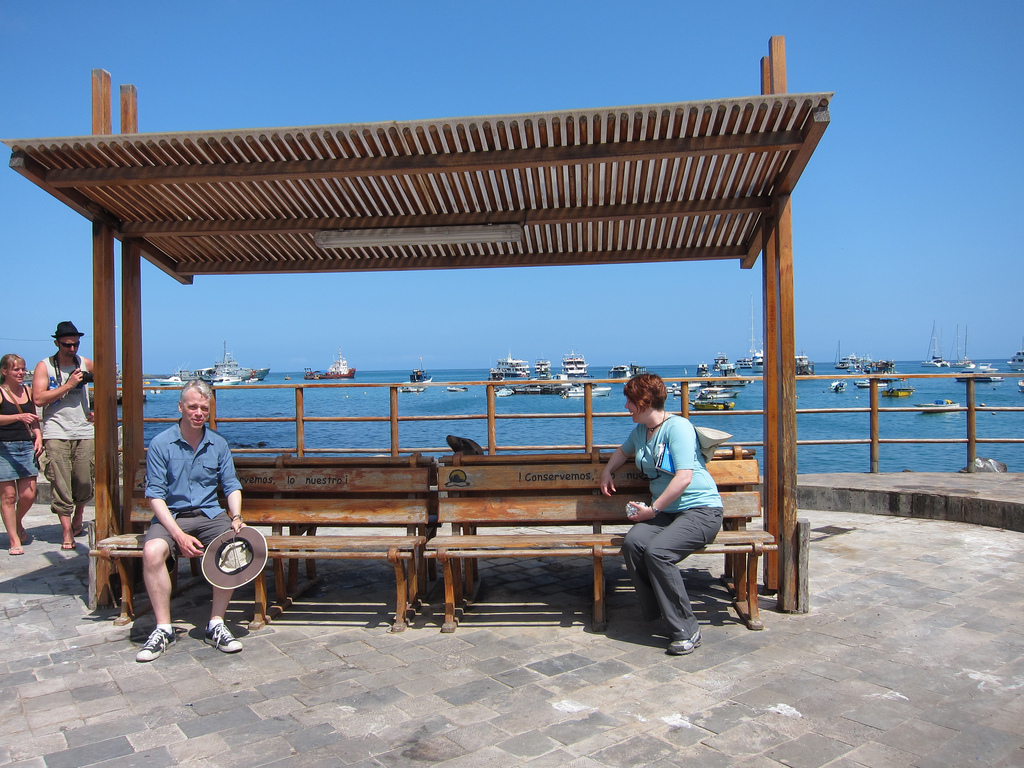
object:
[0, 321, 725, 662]
people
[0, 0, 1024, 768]
outdoors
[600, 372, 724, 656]
woman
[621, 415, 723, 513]
top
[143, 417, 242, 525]
shirt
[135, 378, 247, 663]
man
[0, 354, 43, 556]
woman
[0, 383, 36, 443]
top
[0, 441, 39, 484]
skirt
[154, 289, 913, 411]
boats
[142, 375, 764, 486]
railing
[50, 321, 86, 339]
hat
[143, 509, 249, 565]
shorts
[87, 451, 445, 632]
bench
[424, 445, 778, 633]
bench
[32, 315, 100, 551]
man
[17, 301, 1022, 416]
boat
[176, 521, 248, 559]
hand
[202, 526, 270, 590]
hat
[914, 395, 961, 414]
boat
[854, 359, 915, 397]
boat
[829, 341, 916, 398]
boat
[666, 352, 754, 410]
boat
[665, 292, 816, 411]
boat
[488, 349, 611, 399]
boat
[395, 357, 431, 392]
boat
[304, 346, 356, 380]
boat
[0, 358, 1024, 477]
water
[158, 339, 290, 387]
boat